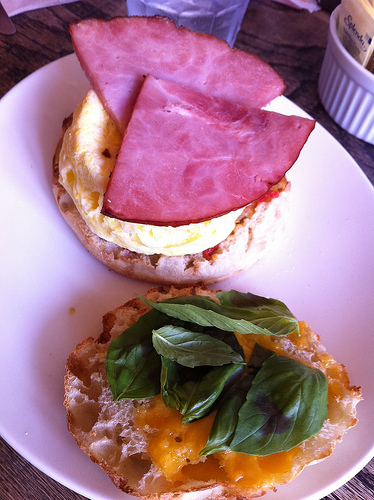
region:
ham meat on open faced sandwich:
[72, 12, 314, 219]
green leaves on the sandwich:
[100, 288, 323, 454]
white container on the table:
[314, 4, 372, 141]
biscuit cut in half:
[46, 88, 344, 492]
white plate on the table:
[5, 39, 372, 498]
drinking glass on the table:
[127, 0, 241, 51]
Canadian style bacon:
[66, 15, 316, 226]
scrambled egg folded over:
[56, 87, 251, 254]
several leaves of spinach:
[104, 289, 327, 457]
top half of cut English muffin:
[61, 286, 364, 499]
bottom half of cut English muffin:
[51, 111, 289, 284]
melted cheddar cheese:
[136, 320, 347, 489]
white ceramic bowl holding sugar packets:
[316, 3, 372, 146]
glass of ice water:
[125, 1, 247, 49]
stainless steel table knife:
[1, 2, 18, 35]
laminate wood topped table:
[0, 0, 373, 192]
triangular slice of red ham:
[97, 80, 323, 221]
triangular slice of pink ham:
[67, 14, 295, 133]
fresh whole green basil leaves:
[93, 282, 334, 454]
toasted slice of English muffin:
[49, 283, 354, 493]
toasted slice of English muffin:
[51, 87, 267, 296]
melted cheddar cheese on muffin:
[127, 314, 348, 487]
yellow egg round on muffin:
[61, 81, 256, 245]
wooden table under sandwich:
[6, 0, 373, 492]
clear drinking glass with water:
[126, 1, 249, 52]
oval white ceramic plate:
[2, 50, 369, 489]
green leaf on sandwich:
[224, 356, 328, 458]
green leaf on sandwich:
[199, 375, 248, 459]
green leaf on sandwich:
[150, 323, 247, 368]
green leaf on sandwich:
[158, 325, 244, 423]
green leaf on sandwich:
[106, 297, 184, 406]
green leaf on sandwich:
[136, 289, 300, 338]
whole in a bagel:
[71, 397, 104, 435]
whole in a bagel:
[68, 357, 103, 398]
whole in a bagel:
[91, 428, 119, 470]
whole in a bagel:
[116, 451, 153, 491]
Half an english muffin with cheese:
[58, 281, 364, 492]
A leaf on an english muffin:
[130, 280, 300, 339]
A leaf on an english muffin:
[148, 323, 247, 365]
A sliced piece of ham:
[105, 72, 317, 224]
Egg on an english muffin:
[58, 88, 242, 248]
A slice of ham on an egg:
[68, 15, 284, 112]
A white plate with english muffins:
[2, 53, 373, 498]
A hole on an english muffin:
[68, 398, 98, 432]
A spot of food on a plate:
[63, 302, 84, 319]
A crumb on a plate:
[19, 428, 31, 439]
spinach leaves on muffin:
[109, 294, 329, 448]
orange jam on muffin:
[121, 318, 355, 488]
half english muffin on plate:
[62, 287, 361, 498]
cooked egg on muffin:
[64, 88, 255, 250]